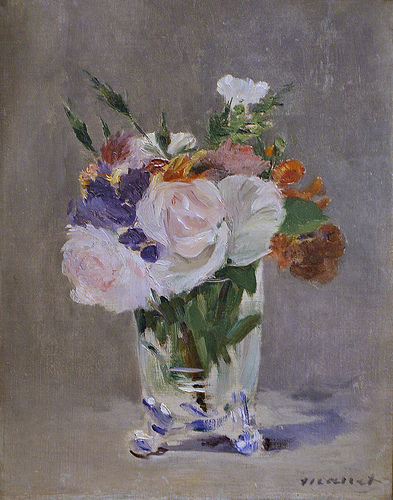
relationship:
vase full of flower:
[128, 259, 264, 457] [211, 69, 279, 120]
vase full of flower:
[128, 259, 264, 457] [264, 221, 349, 290]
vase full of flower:
[128, 259, 264, 457] [189, 131, 273, 184]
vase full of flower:
[128, 259, 264, 457] [59, 156, 155, 235]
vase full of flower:
[128, 259, 264, 457] [53, 218, 170, 316]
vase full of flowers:
[119, 278, 263, 435] [39, 60, 353, 317]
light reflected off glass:
[163, 357, 210, 402] [119, 256, 268, 455]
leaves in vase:
[194, 299, 242, 348] [102, 244, 284, 466]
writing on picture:
[296, 470, 382, 488] [8, 10, 387, 496]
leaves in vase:
[135, 258, 263, 377] [128, 257, 266, 459]